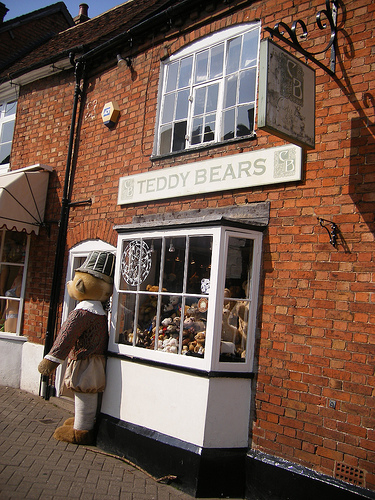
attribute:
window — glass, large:
[151, 23, 261, 162]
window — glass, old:
[1, 89, 21, 171]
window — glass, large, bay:
[105, 229, 261, 379]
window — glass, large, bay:
[2, 226, 32, 337]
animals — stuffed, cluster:
[122, 279, 251, 361]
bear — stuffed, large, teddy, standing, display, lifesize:
[39, 250, 117, 445]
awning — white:
[0, 165, 54, 238]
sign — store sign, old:
[255, 39, 315, 151]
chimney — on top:
[72, 4, 93, 25]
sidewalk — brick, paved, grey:
[2, 387, 204, 499]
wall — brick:
[1, 1, 373, 492]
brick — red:
[287, 306, 315, 315]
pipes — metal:
[39, 0, 197, 398]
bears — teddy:
[125, 284, 250, 361]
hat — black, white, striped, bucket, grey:
[69, 246, 114, 286]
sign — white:
[117, 141, 304, 205]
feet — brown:
[54, 417, 98, 447]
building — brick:
[0, 2, 374, 500]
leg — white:
[65, 352, 105, 432]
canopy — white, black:
[1, 168, 54, 233]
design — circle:
[118, 240, 152, 284]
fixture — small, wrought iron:
[312, 217, 337, 251]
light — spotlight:
[111, 52, 134, 74]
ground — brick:
[2, 384, 197, 498]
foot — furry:
[55, 425, 95, 446]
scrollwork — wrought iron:
[263, 2, 340, 81]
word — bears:
[137, 158, 269, 198]